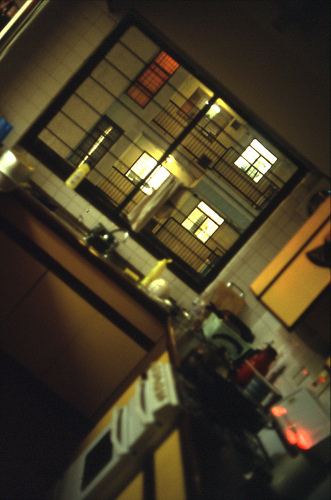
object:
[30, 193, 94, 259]
sink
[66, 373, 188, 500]
oven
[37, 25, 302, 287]
window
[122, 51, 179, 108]
light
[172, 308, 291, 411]
pot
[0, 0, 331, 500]
board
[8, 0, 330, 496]
tile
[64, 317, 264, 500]
cooker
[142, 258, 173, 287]
bottle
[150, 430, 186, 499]
drawer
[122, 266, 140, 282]
soap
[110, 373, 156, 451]
handle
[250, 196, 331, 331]
cabinet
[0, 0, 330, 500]
building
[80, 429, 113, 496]
glass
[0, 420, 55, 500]
floor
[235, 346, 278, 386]
container